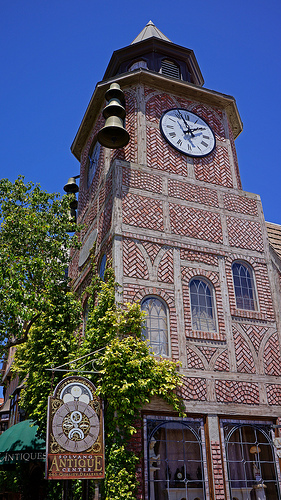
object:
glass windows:
[143, 416, 207, 497]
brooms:
[1, 174, 180, 499]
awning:
[1, 418, 46, 468]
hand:
[177, 109, 194, 138]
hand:
[184, 127, 206, 134]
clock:
[159, 107, 214, 158]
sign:
[43, 372, 108, 483]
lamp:
[250, 446, 262, 466]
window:
[222, 423, 280, 498]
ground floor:
[105, 401, 278, 498]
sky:
[6, 18, 68, 132]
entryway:
[2, 419, 49, 498]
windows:
[133, 249, 261, 370]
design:
[241, 333, 269, 354]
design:
[159, 202, 218, 233]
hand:
[174, 125, 203, 132]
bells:
[95, 79, 129, 151]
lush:
[0, 169, 185, 498]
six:
[187, 144, 191, 150]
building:
[0, 19, 280, 494]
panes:
[227, 439, 260, 480]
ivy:
[52, 255, 187, 495]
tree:
[22, 273, 184, 498]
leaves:
[37, 283, 169, 391]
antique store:
[0, 327, 106, 498]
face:
[170, 111, 212, 147]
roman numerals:
[175, 134, 186, 148]